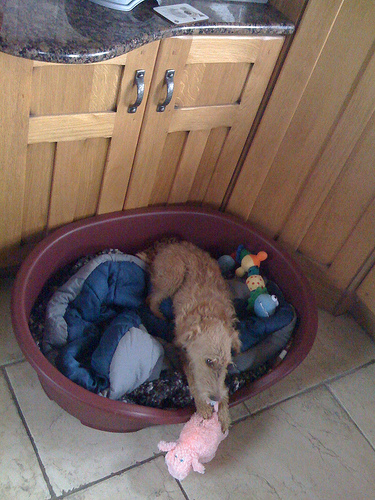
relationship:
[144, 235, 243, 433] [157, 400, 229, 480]
brown dog holding pig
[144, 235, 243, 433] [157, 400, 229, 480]
brown dog lying pig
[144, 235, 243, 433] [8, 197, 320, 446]
brown dog in basket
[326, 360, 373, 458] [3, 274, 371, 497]
tile on floor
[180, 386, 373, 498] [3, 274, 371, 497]
tile on floor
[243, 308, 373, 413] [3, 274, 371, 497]
tile on floor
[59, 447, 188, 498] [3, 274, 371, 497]
tile on floor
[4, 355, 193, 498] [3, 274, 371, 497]
tile on floor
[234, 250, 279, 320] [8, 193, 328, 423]
playtoy in basket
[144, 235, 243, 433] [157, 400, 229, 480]
brown dog chewing on pig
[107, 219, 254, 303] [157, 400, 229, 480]
brown dog chewing pig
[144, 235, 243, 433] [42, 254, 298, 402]
brown dog on bed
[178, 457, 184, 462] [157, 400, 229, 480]
eye on pig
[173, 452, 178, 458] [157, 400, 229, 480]
eye on pig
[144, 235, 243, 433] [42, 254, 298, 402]
brown dog sleeping bed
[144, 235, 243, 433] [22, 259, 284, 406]
brown dog in bed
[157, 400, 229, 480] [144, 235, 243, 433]
pig for brown dog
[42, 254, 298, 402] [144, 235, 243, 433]
bed for brown dog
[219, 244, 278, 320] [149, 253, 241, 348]
playtoy for dog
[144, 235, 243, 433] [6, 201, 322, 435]
brown dog in bed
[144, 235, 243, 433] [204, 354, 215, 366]
brown dog in eye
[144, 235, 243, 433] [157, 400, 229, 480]
brown dog chewing pig